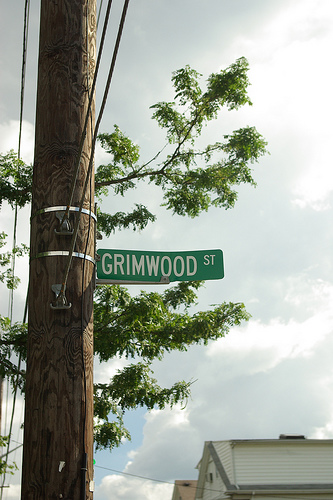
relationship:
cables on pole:
[66, 2, 128, 294] [20, 1, 94, 492]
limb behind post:
[94, 282, 240, 353] [28, 2, 96, 497]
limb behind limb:
[4, 319, 23, 379] [94, 282, 240, 353]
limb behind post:
[93, 362, 193, 449] [28, 2, 96, 497]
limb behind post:
[4, 151, 33, 208] [28, 2, 96, 497]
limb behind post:
[94, 52, 268, 232] [28, 2, 96, 497]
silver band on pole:
[29, 205, 99, 216] [16, 2, 106, 496]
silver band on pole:
[27, 248, 100, 264] [16, 2, 106, 496]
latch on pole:
[49, 282, 71, 310] [15, 0, 98, 499]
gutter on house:
[229, 440, 241, 492] [170, 423, 318, 491]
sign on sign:
[95, 246, 225, 284] [91, 247, 234, 293]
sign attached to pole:
[95, 246, 225, 284] [20, 1, 97, 491]